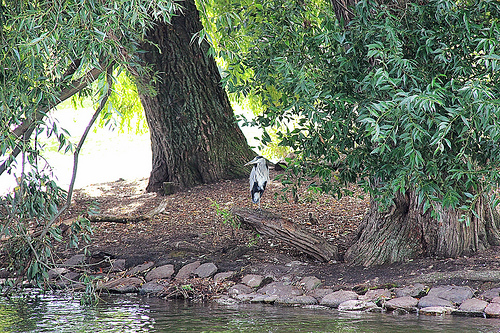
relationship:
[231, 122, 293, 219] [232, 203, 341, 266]
bird standing standing on log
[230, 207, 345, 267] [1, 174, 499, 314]
log laying on ground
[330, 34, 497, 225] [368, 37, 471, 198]
vegetation growing from tree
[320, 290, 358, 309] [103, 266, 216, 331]
rock near water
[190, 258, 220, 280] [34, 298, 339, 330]
rock near water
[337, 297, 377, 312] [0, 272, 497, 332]
rock near water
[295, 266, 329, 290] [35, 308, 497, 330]
rock near water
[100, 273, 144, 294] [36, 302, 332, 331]
rock near water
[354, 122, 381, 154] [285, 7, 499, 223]
part of a bush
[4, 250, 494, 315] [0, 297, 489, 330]
rocks on water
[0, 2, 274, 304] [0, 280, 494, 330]
tree reflecting in water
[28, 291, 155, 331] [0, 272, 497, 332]
sunlight reflecting reflecting on water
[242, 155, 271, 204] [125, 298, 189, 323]
bird by water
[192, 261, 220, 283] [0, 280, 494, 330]
rock near water